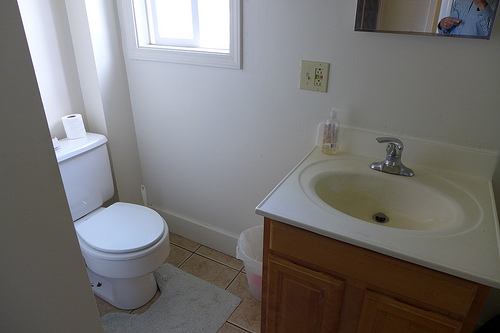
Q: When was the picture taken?
A: Daytime.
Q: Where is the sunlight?
A: Outside the window.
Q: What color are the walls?
A: White.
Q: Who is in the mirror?
A: A person.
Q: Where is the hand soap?
A: On the sink.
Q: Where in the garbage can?
A: On the floor next to the sink.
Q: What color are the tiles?
A: Light brown or tan.